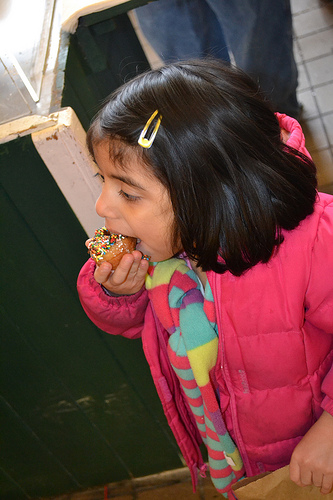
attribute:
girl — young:
[77, 59, 331, 468]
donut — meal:
[88, 231, 141, 267]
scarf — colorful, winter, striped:
[147, 260, 244, 494]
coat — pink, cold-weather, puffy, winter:
[75, 192, 332, 474]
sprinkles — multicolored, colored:
[90, 232, 123, 259]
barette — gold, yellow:
[135, 108, 167, 146]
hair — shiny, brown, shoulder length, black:
[96, 68, 301, 256]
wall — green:
[0, 134, 197, 481]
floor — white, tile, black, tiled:
[297, 6, 332, 137]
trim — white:
[30, 121, 96, 228]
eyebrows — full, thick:
[110, 175, 142, 186]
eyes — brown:
[121, 188, 146, 200]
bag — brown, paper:
[236, 475, 332, 498]